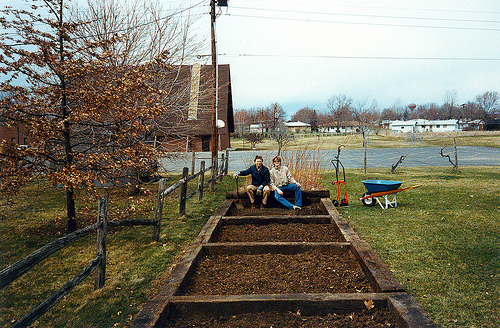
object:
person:
[236, 154, 270, 210]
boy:
[268, 156, 302, 213]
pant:
[274, 183, 302, 210]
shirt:
[270, 166, 296, 191]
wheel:
[362, 193, 377, 207]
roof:
[127, 64, 231, 139]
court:
[148, 205, 408, 328]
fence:
[0, 151, 230, 327]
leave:
[112, 62, 172, 140]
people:
[269, 155, 302, 210]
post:
[208, 0, 234, 181]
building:
[386, 118, 485, 133]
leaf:
[363, 298, 375, 310]